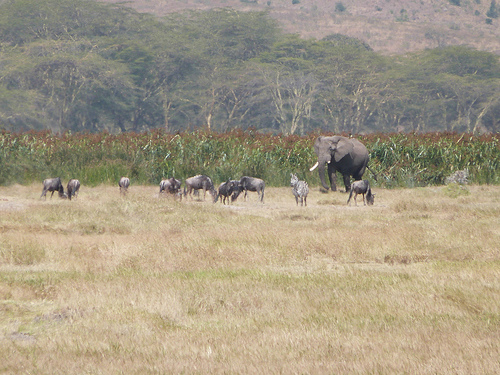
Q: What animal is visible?
A: An elephant.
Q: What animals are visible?
A: Elephants.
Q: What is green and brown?
A: Grass.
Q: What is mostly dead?
A: Grass.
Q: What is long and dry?
A: Grass.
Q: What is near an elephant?
A: A herd of animals.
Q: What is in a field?
A: Brown grass.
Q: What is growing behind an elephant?
A: Plants.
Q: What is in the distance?
A: Trees.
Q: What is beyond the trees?
A: A hillside.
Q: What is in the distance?
A: A forest.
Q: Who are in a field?
A: Animals.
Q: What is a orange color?
A: Flowers.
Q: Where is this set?
A: Jungle.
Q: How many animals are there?
A: Twelve.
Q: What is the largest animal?
A: Elephant.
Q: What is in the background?
A: Trees.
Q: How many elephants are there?
A: One.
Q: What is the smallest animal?
A: Zebra.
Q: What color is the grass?
A: Brown.